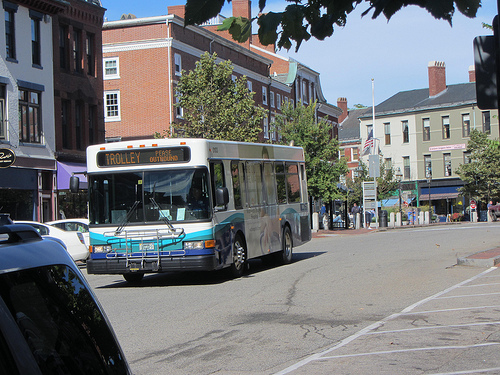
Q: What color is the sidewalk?
A: Red.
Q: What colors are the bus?
A: White and blue.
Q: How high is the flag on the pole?
A: Halfway.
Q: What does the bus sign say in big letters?
A: Trolley.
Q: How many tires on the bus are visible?
A: 3.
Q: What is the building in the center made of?
A: Brick.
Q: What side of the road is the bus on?
A: The right side.